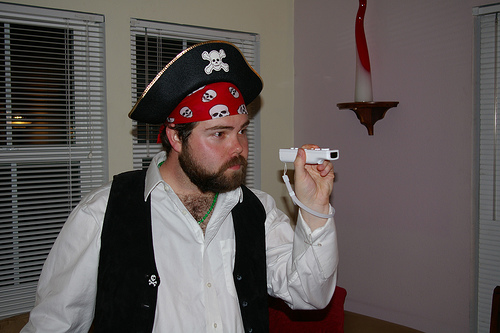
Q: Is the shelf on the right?
A: Yes, the shelf is on the right of the image.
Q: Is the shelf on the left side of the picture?
A: No, the shelf is on the right of the image.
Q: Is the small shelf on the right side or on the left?
A: The shelf is on the right of the image.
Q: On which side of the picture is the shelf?
A: The shelf is on the right of the image.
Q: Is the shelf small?
A: Yes, the shelf is small.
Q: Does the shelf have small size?
A: Yes, the shelf is small.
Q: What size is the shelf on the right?
A: The shelf is small.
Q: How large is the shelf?
A: The shelf is small.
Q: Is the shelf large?
A: No, the shelf is small.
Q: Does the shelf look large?
A: No, the shelf is small.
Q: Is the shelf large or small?
A: The shelf is small.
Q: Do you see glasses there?
A: No, there are no glasses.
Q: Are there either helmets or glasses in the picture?
A: No, there are no glasses or helmets.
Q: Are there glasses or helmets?
A: No, there are no glasses or helmets.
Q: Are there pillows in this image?
A: No, there are no pillows.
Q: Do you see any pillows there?
A: No, there are no pillows.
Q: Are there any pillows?
A: No, there are no pillows.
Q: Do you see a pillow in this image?
A: No, there are no pillows.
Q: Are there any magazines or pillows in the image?
A: No, there are no pillows or magazines.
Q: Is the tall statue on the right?
A: Yes, the statue is on the right of the image.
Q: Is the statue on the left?
A: No, the statue is on the right of the image.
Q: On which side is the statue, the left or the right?
A: The statue is on the right of the image.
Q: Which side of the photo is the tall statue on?
A: The statue is on the right of the image.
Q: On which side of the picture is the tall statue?
A: The statue is on the right of the image.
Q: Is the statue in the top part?
A: Yes, the statue is in the top of the image.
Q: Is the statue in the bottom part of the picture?
A: No, the statue is in the top of the image.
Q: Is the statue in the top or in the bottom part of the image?
A: The statue is in the top of the image.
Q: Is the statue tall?
A: Yes, the statue is tall.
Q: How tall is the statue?
A: The statue is tall.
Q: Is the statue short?
A: No, the statue is tall.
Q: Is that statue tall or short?
A: The statue is tall.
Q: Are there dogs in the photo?
A: No, there are no dogs.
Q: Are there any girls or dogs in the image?
A: No, there are no dogs or girls.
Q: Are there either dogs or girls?
A: No, there are no dogs or girls.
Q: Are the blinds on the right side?
A: No, the blinds are on the left of the image.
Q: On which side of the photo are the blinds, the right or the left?
A: The blinds are on the left of the image.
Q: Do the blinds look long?
A: Yes, the blinds are long.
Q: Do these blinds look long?
A: Yes, the blinds are long.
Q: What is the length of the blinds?
A: The blinds are long.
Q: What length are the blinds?
A: The blinds are long.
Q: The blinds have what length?
A: The blinds are long.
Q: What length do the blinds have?
A: The blinds have long length.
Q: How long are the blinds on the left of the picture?
A: The blinds are long.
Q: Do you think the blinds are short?
A: No, the blinds are long.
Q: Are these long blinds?
A: Yes, these are long blinds.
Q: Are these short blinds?
A: No, these are long blinds.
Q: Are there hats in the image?
A: Yes, there is a hat.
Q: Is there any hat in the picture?
A: Yes, there is a hat.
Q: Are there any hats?
A: Yes, there is a hat.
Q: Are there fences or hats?
A: Yes, there is a hat.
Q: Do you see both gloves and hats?
A: No, there is a hat but no gloves.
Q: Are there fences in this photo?
A: No, there are no fences.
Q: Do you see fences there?
A: No, there are no fences.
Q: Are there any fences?
A: No, there are no fences.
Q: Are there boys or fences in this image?
A: No, there are no fences or boys.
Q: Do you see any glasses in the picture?
A: No, there are no glasses.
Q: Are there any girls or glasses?
A: No, there are no glasses or girls.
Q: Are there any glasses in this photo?
A: No, there are no glasses.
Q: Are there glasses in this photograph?
A: No, there are no glasses.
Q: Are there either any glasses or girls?
A: No, there are no glasses or girls.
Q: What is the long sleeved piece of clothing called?
A: The clothing item is a shirt.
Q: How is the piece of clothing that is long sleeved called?
A: The clothing item is a shirt.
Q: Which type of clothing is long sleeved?
A: The clothing is a shirt.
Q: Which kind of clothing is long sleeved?
A: The clothing is a shirt.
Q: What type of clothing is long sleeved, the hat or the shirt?
A: The shirt is long sleeved.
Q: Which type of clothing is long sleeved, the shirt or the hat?
A: The shirt is long sleeved.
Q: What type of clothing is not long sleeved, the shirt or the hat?
A: The hat is not long sleeved.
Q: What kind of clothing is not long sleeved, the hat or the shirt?
A: The hat is not long sleeved.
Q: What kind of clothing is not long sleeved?
A: The clothing is a hat.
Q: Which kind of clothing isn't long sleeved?
A: The clothing is a hat.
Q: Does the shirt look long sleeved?
A: Yes, the shirt is long sleeved.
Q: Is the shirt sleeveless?
A: No, the shirt is long sleeved.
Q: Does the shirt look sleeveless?
A: No, the shirt is long sleeved.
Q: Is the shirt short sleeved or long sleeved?
A: The shirt is long sleeved.